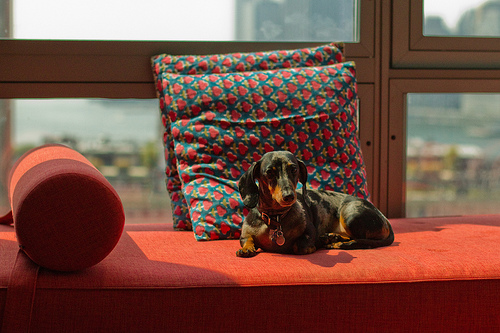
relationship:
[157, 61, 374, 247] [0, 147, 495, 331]
pillow on couch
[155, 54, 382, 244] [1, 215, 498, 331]
pillow on couch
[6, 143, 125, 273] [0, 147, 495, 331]
pillow on couch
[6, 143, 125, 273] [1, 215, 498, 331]
pillow on couch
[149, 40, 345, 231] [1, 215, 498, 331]
pillow on couch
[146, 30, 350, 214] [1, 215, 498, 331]
pillow on couch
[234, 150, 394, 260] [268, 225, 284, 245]
dachshund wearing tags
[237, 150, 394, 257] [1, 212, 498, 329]
dachshund on bed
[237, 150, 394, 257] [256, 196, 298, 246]
dachshund wearing dog collar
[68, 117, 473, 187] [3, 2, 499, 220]
view outside window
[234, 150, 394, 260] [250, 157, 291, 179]
dachshund has eyes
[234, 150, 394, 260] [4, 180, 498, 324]
dachshund on couch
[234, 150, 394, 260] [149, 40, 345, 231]
dachshund leaning against pillow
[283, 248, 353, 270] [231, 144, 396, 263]
shadow of dog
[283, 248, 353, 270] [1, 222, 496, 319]
shadow on couch